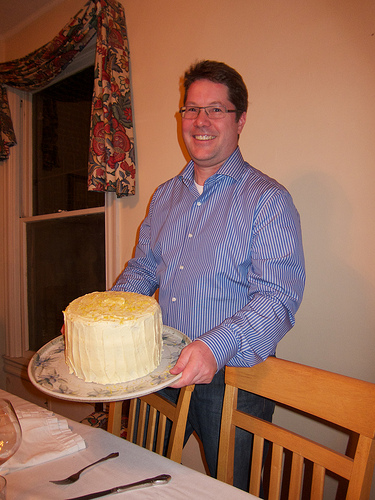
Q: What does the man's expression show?
A: He is content.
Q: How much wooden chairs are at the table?
A: Two.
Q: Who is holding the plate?
A: The man.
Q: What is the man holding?
A: Plate with cake.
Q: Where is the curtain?
A: Over the window.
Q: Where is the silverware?
A: On the table.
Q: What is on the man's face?
A: Glasses.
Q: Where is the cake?
A: On the plate.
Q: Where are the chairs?
A: By the table.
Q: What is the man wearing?
A: Striped shirt and blue jeans.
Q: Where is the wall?
A: Behind the man.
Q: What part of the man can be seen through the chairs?
A: Legs.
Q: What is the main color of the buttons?
A: White.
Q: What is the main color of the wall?
A: White.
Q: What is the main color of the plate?
A: White.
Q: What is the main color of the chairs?
A: Brown.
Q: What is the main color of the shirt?
A: Blue.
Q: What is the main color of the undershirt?
A: White.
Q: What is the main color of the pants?
A: Blue.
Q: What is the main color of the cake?
A: Yellow.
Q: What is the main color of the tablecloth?
A: White.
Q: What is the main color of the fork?
A: Gray.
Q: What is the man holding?
A: A cake.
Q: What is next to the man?
A: A window.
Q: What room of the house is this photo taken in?
A: Dining room.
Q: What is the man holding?
A: Cake.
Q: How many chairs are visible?
A: Two.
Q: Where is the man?
A: Behind the chairs.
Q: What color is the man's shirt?
A: Blue.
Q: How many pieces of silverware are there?
A: Two.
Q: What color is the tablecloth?
A: White.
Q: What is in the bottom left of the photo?
A: A chair.